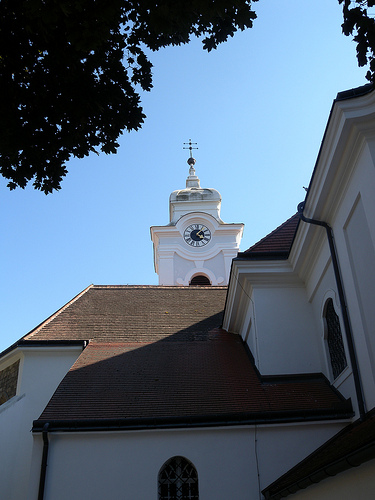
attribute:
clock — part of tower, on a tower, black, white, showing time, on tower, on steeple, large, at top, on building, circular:
[184, 224, 213, 247]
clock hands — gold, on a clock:
[197, 232, 209, 244]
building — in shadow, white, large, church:
[4, 86, 374, 498]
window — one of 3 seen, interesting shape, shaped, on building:
[320, 300, 351, 382]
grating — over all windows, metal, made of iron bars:
[173, 464, 185, 499]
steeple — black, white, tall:
[150, 139, 238, 283]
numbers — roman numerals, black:
[203, 229, 211, 247]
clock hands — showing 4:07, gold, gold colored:
[197, 231, 207, 240]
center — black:
[192, 230, 204, 240]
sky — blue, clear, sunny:
[192, 46, 301, 163]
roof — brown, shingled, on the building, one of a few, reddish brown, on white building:
[31, 288, 356, 431]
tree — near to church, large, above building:
[0, 0, 258, 194]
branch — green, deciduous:
[337, 1, 374, 81]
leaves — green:
[355, 33, 368, 67]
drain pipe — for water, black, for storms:
[299, 190, 369, 416]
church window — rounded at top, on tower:
[190, 273, 210, 287]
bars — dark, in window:
[164, 479, 198, 496]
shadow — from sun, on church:
[53, 315, 337, 429]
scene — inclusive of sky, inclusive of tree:
[3, 3, 374, 500]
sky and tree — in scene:
[4, 0, 302, 204]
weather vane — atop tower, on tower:
[184, 136, 198, 165]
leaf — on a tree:
[203, 38, 217, 52]